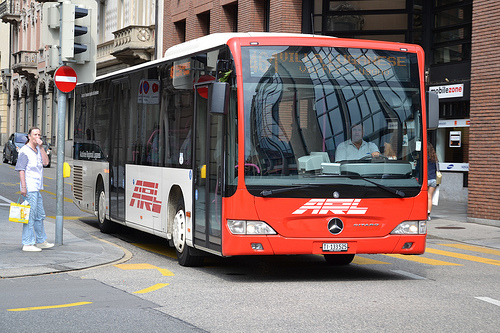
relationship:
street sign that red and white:
[55, 46, 85, 112] [57, 76, 78, 87]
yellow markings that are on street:
[126, 262, 168, 295] [231, 298, 394, 323]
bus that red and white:
[214, 24, 424, 247] [57, 76, 78, 87]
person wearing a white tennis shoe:
[11, 126, 55, 255] [23, 241, 44, 255]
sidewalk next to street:
[17, 249, 94, 267] [231, 298, 394, 323]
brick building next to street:
[474, 42, 495, 165] [231, 298, 394, 323]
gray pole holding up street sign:
[52, 103, 69, 217] [55, 46, 85, 112]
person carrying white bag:
[426, 139, 444, 218] [431, 183, 445, 206]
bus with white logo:
[214, 24, 424, 247] [297, 197, 366, 217]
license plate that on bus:
[319, 240, 348, 253] [214, 24, 424, 247]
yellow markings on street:
[126, 262, 168, 295] [231, 298, 394, 323]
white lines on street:
[461, 286, 499, 310] [231, 298, 394, 323]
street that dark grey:
[231, 298, 394, 323] [97, 312, 161, 331]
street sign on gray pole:
[55, 46, 85, 112] [52, 103, 69, 217]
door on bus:
[195, 84, 222, 251] [214, 24, 424, 247]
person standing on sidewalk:
[11, 126, 55, 255] [17, 249, 94, 267]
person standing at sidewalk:
[11, 126, 55, 255] [17, 249, 94, 267]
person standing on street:
[11, 126, 55, 255] [231, 298, 394, 323]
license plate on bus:
[319, 240, 348, 253] [214, 24, 424, 247]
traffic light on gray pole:
[62, 2, 89, 63] [52, 103, 69, 217]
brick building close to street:
[474, 42, 495, 165] [231, 298, 394, 323]